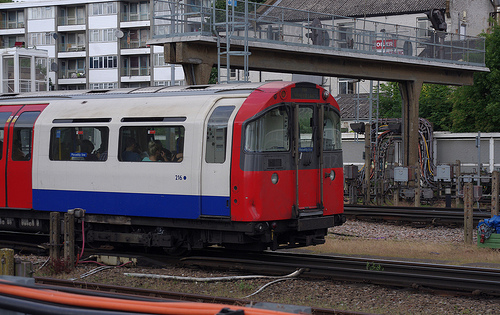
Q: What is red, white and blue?
A: The train.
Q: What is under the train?
A: Tracks.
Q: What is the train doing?
A: Moving.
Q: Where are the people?
A: In the train.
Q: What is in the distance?
A: Building.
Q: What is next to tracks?
A: Rocks.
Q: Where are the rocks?
A: On the ground.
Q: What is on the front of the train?
A: Window.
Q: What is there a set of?
A: Train tracks.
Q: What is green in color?
A: Leaves on the tree.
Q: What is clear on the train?
A: Windows.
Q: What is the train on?
A: Tracks.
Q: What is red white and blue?
A: Train.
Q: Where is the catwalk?
A: Above the train.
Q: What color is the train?
A: Red, white and blue.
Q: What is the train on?
A: Tracks.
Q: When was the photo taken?
A: Afternoon.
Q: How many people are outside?
A: None.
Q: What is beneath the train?
A: Tracks.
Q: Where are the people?
A: On the train.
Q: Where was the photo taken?
A: By a railway.